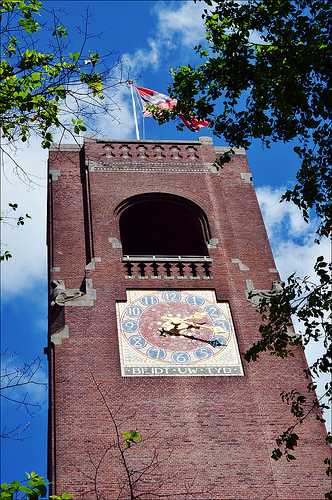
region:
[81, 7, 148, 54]
The sky is very clear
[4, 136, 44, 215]
The clouds are white and fluffy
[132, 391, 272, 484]
The building is made of brick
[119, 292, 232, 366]
The clock on the tower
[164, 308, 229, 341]
The hands on the clock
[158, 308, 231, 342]
The hands on the clock are gold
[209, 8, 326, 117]
The leaves on the tree are green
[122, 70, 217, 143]
The flag on top of the building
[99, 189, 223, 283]
The arch way on top of the building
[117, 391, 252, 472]
The color of the brick is red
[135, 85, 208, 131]
a flag is waving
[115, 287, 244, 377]
clock on the tower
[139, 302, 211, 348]
center circle is red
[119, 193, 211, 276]
balcony in the tower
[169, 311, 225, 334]
clock hands are white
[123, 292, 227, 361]
clock numbers are white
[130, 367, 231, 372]
the text is white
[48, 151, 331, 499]
red bricks on tower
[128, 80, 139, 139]
a large flag pole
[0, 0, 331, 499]
trees with green leaves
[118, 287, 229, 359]
an outdoor painted wall clock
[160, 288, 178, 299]
painted clock hour number 12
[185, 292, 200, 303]
painted clock hour number 1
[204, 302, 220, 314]
painted clock hour number 2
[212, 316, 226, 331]
painted clock hour number 3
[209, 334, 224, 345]
painted clock hour number 4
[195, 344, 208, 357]
painted clock hour number 5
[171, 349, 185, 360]
painted clock hour number 6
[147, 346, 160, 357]
painted clock hour number 7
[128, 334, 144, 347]
painted clock hour number 8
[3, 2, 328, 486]
clouds in blue sky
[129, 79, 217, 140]
flying flag on pole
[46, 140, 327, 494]
tower made of red brick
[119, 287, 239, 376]
clock on tower wall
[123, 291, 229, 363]
numbers in blue circles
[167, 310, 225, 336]
two gold clock hands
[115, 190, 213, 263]
arched opening in tower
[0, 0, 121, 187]
green leaves on branches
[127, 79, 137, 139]
flag pole on top of tower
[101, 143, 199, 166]
design elements on tower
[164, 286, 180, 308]
number twelve on clock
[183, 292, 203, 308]
number one on clock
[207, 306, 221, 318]
number two on clock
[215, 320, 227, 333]
number three on clock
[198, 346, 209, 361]
number five on clock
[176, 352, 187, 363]
number six on clock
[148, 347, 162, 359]
number seven on clock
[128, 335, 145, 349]
number eight on clock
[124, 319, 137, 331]
number nine on clock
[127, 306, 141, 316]
number ten on clock